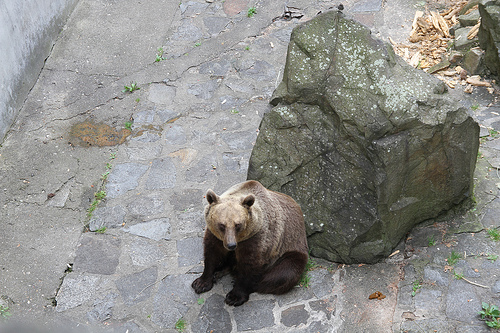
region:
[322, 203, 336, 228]
the stone is big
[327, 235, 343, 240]
the stone is big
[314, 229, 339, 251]
the stone is big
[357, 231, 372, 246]
the stone is big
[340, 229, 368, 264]
the stone is big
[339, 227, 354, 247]
the stone is big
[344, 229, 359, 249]
the stone is big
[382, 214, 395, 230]
the stone is big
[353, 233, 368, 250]
the stone is big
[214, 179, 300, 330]
A bear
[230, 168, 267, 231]
A bear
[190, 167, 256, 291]
A bear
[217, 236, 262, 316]
A bear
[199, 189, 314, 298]
Brown grizzly bear is sitting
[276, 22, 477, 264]
Large grey rock in background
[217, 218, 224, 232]
Bear's left eye is black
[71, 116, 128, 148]
Orange splatter on the rocks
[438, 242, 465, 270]
Small green plants growing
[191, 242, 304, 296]
Bear's lower half and paws are black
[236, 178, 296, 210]
Ridge of bear's back looks powerful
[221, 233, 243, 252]
Bear's muzzle is relatively short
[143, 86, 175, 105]
Small flat stone in pavement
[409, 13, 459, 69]
Small pieces of rock in background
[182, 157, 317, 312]
large brown bear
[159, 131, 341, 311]
large brown bear sitting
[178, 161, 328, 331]
brown bear sitting on a rocky surface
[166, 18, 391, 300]
large boulder behind a brown bear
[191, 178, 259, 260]
the head of a brown bear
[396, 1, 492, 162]
wood laying behind a large boulder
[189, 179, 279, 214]
the ears of a brown bear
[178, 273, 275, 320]
two large brown bear paws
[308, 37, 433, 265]
cracks and crevices in a large boulder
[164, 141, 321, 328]
large brown bear looking off into the distance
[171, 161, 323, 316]
a bear sitting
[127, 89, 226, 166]
flag stone platform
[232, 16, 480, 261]
a large grey boulder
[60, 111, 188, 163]
smeared bear poop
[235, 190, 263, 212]
a fuzzy ear of a bear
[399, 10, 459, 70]
a pile of chipped wood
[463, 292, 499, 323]
a small weed growing through stone patio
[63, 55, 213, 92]
cracks in a stone patio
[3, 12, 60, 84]
a concrete wall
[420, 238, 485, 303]
sticks and leaves